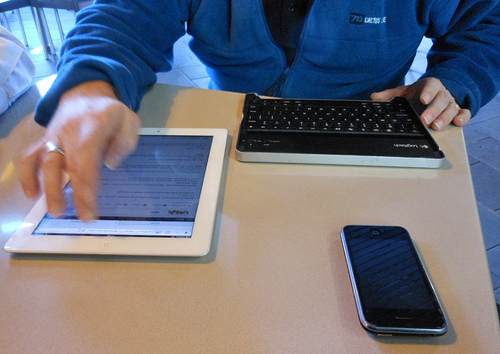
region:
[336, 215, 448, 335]
cell phone on the table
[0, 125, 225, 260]
ipad on the table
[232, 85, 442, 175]
keyboard on the table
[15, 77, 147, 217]
person's left hand touching the ipad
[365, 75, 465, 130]
person's left hand resting on the table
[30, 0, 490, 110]
person in blue shirt touching an ipad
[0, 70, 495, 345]
tan colored table top with technology items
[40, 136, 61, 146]
silver ring on the person's finger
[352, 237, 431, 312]
reflection on the cellphone screen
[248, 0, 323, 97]
zipper on the person's jacket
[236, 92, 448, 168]
A black, wireless tablet keyboard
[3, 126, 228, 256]
A white iPad displaying a web browser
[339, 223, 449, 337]
A black iPhone, screen off, set aside on the table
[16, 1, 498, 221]
A man in a blue jacket using a tablet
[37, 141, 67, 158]
A ring on the person's right ring finger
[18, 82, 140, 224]
The person's right hand, navigating the iPad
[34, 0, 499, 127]
A fleece blue jacket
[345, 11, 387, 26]
A logo on the left breast of the jacket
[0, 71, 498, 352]
A shiny light brown table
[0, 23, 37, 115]
A stack of white towels or blankets on the table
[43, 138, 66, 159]
the man is wearing a ring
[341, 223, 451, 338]
a smart phone is on the table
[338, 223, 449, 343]
the smart phone is turned off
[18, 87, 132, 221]
the man is typing on the tablet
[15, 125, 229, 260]
the tablet is white in color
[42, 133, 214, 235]
the screen is turned on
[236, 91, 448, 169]
a keyboard is on the table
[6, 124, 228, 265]
the tablet is on the table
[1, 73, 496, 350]
the table is made of wood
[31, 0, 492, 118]
the man is wearing a jacket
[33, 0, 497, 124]
a woman wearing a blue sweater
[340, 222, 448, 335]
a silvery cell phone on a desk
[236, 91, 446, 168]
a black keyboard on a wooden desk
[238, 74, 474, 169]
woman touching a black keyboard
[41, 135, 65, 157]
woman wearing an engagement ring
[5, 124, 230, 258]
a white tablet on a desk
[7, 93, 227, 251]
a woman typing on a white tablet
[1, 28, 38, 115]
a white bag on a desk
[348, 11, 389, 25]
a logo on a sweater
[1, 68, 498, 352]
a wooden desk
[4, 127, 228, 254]
a tablet with white trim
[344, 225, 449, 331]
a black and silver cellphone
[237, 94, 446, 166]
a black and silver keyboard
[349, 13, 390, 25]
a logo on a blue shirt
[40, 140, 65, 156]
a sparkling ring on a finger on the right hand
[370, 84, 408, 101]
a thumb on a person's left hand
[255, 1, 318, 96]
a blue zipper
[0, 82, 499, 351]
a light brown table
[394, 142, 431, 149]
a white logo on a black keyboard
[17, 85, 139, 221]
a person's right hand